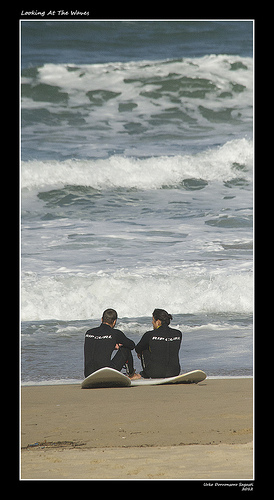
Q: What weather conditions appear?
A: It is sunny.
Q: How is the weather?
A: It is sunny.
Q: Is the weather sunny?
A: Yes, it is sunny.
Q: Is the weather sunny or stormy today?
A: It is sunny.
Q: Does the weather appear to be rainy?
A: No, it is sunny.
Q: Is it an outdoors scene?
A: Yes, it is outdoors.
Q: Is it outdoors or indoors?
A: It is outdoors.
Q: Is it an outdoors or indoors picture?
A: It is outdoors.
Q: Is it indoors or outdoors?
A: It is outdoors.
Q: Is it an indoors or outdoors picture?
A: It is outdoors.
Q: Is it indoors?
A: No, it is outdoors.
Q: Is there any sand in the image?
A: Yes, there is sand.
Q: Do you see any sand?
A: Yes, there is sand.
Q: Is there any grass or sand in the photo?
A: Yes, there is sand.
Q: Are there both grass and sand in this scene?
A: No, there is sand but no grass.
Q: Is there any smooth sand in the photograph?
A: Yes, there is smooth sand.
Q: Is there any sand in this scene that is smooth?
A: Yes, there is sand that is smooth.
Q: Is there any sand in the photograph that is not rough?
A: Yes, there is smooth sand.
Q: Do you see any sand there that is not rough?
A: Yes, there is smooth sand.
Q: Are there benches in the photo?
A: No, there are no benches.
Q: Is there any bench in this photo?
A: No, there are no benches.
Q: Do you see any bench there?
A: No, there are no benches.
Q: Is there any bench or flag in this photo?
A: No, there are no benches or flags.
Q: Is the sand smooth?
A: Yes, the sand is smooth.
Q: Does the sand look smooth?
A: Yes, the sand is smooth.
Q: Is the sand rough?
A: No, the sand is smooth.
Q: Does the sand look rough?
A: No, the sand is smooth.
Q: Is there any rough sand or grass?
A: No, there is sand but it is smooth.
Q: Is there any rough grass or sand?
A: No, there is sand but it is smooth.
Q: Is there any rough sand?
A: No, there is sand but it is smooth.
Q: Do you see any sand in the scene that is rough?
A: No, there is sand but it is smooth.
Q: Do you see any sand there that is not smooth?
A: No, there is sand but it is smooth.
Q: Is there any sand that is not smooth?
A: No, there is sand but it is smooth.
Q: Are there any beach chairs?
A: No, there are no beach chairs.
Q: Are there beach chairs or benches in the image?
A: No, there are no beach chairs or benches.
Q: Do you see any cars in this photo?
A: No, there are no cars.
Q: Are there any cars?
A: No, there are no cars.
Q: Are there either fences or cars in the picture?
A: No, there are no cars or fences.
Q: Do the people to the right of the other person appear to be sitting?
A: Yes, the people are sitting.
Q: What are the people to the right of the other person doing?
A: The people are sitting.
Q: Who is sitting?
A: The people are sitting.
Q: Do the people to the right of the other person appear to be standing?
A: No, the people are sitting.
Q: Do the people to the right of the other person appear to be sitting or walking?
A: The people are sitting.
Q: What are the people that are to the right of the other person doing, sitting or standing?
A: The people are sitting.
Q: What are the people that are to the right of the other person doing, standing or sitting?
A: The people are sitting.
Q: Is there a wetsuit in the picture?
A: Yes, there is a wetsuit.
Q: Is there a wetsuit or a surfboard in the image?
A: Yes, there is a wetsuit.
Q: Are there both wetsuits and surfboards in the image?
A: Yes, there are both a wetsuit and a surfboard.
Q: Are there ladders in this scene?
A: No, there are no ladders.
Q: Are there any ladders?
A: No, there are no ladders.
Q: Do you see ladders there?
A: No, there are no ladders.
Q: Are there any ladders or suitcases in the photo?
A: No, there are no ladders or suitcases.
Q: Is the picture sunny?
A: Yes, the picture is sunny.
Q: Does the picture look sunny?
A: Yes, the picture is sunny.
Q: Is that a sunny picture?
A: Yes, that is a sunny picture.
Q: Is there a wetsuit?
A: Yes, there is a wetsuit.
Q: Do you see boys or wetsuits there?
A: Yes, there is a wetsuit.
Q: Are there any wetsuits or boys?
A: Yes, there is a wetsuit.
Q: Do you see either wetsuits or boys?
A: Yes, there is a wetsuit.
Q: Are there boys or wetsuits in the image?
A: Yes, there is a wetsuit.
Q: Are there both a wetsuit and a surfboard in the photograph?
A: Yes, there are both a wetsuit and a surfboard.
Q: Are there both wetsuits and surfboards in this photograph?
A: Yes, there are both a wetsuit and a surfboard.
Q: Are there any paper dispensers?
A: No, there are no paper dispensers.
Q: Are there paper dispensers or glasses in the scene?
A: No, there are no paper dispensers or glasses.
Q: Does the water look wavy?
A: Yes, the water is wavy.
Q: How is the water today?
A: The water is wavy.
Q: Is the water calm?
A: No, the water is wavy.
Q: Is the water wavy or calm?
A: The water is wavy.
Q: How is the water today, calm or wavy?
A: The water is wavy.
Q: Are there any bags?
A: No, there are no bags.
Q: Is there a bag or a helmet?
A: No, there are no bags or helmets.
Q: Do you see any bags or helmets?
A: No, there are no bags or helmets.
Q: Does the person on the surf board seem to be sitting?
A: Yes, the person is sitting.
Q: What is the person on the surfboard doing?
A: The person is sitting.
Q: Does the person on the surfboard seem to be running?
A: No, the person is sitting.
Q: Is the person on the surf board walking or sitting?
A: The person is sitting.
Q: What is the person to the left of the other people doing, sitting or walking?
A: The person is sitting.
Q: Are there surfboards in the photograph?
A: Yes, there is a surfboard.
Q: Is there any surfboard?
A: Yes, there is a surfboard.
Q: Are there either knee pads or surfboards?
A: Yes, there is a surfboard.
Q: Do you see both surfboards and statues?
A: No, there is a surfboard but no statues.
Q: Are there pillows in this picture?
A: No, there are no pillows.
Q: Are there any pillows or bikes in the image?
A: No, there are no pillows or bikes.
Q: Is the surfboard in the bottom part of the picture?
A: Yes, the surfboard is in the bottom of the image.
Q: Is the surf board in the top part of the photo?
A: No, the surf board is in the bottom of the image.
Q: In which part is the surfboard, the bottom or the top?
A: The surfboard is in the bottom of the image.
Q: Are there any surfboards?
A: Yes, there is a surfboard.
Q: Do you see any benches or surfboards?
A: Yes, there is a surfboard.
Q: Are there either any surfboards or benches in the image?
A: Yes, there is a surfboard.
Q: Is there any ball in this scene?
A: No, there are no balls.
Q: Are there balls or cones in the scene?
A: No, there are no balls or cones.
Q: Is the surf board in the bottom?
A: Yes, the surf board is in the bottom of the image.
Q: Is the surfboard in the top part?
A: No, the surfboard is in the bottom of the image.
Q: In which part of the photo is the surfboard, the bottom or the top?
A: The surfboard is in the bottom of the image.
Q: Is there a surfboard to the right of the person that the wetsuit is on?
A: Yes, there is a surfboard to the right of the person.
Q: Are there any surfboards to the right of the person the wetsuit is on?
A: Yes, there is a surfboard to the right of the person.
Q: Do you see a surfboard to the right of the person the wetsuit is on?
A: Yes, there is a surfboard to the right of the person.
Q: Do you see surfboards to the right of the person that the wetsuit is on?
A: Yes, there is a surfboard to the right of the person.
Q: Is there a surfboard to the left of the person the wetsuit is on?
A: No, the surfboard is to the right of the person.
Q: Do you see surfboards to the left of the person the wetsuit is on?
A: No, the surfboard is to the right of the person.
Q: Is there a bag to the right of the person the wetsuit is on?
A: No, there is a surfboard to the right of the person.